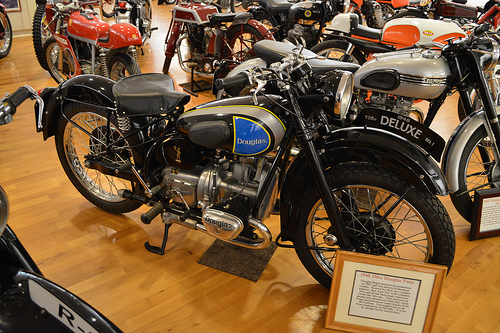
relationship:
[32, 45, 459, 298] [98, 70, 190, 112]
motorcycles has seat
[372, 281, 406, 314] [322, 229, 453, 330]
writing on frame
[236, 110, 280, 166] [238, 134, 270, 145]
logo says douglas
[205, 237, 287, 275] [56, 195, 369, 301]
rug on ground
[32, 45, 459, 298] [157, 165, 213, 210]
motorcycles has tank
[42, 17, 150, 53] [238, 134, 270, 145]
motorcycle says douglas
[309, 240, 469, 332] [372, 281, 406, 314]
photo has writing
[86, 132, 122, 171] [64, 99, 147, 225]
spokes on wheel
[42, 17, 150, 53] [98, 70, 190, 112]
motorcycle has seat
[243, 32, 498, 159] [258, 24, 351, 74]
motorcycle has seat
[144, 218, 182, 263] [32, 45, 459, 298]
kickstand on motorcycles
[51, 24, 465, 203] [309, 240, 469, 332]
motorcycles in photo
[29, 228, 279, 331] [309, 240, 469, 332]
floor in photo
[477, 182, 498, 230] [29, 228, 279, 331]
certificate on floor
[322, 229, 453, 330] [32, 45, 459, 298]
sign by motorcycles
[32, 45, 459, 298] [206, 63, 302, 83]
motorcycles has handle bars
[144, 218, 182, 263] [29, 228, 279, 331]
kickstand on floor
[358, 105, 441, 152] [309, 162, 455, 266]
sign on wheel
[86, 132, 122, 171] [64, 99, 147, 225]
spokes inside wheel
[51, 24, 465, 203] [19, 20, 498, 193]
motorcycles on display